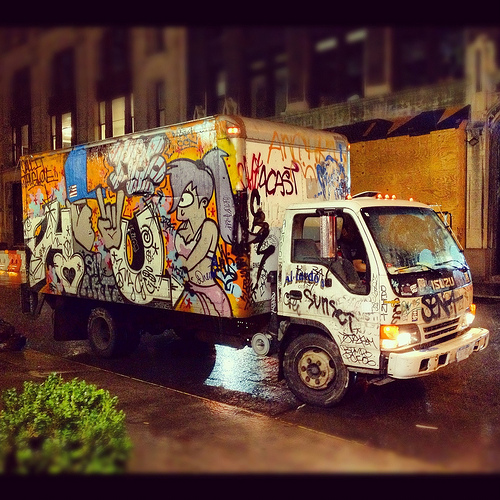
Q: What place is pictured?
A: It is a pavement.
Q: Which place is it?
A: It is a pavement.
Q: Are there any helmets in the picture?
A: No, there are no helmets.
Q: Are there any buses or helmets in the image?
A: No, there are no helmets or buses.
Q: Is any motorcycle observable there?
A: No, there are no motorcycles.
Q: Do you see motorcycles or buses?
A: No, there are no motorcycles or buses.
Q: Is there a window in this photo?
A: Yes, there are windows.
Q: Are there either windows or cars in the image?
A: Yes, there are windows.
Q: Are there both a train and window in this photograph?
A: No, there are windows but no trains.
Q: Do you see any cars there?
A: No, there are no cars.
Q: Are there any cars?
A: No, there are no cars.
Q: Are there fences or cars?
A: No, there are no cars or fences.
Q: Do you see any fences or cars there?
A: No, there are no cars or fences.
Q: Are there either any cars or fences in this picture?
A: No, there are no cars or fences.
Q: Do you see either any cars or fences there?
A: No, there are no cars or fences.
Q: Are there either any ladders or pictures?
A: No, there are no pictures or ladders.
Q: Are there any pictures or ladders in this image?
A: No, there are no pictures or ladders.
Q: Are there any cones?
A: No, there are no cones.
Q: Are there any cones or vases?
A: No, there are no cones or vases.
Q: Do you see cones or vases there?
A: No, there are no cones or vases.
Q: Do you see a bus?
A: No, there are no buses.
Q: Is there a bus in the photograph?
A: No, there are no buses.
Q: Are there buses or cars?
A: No, there are no buses or cars.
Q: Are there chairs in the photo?
A: No, there are no chairs.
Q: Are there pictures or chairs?
A: No, there are no chairs or pictures.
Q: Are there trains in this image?
A: No, there are no trains.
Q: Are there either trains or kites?
A: No, there are no trains or kites.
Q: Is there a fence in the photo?
A: No, there are no fences.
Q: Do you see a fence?
A: No, there are no fences.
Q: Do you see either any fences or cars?
A: No, there are no fences or cars.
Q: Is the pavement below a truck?
A: Yes, the pavement is below a truck.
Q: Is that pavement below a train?
A: No, the pavement is below a truck.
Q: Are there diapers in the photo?
A: No, there are no diapers.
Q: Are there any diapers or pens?
A: No, there are no diapers or pens.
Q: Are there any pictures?
A: No, there are no pictures.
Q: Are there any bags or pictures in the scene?
A: No, there are no pictures or bags.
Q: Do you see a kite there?
A: No, there are no kites.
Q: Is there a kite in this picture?
A: No, there are no kites.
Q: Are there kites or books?
A: No, there are no kites or books.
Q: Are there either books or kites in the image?
A: No, there are no kites or books.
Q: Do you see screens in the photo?
A: No, there are no screens.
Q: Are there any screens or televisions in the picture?
A: No, there are no screens or televisions.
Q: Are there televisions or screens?
A: No, there are no screens or televisions.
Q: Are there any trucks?
A: Yes, there is a truck.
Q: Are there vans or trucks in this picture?
A: Yes, there is a truck.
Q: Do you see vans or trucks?
A: Yes, there is a truck.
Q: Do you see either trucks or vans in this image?
A: Yes, there is a truck.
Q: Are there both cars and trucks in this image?
A: No, there is a truck but no cars.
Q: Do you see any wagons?
A: No, there are no wagons.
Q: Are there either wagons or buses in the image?
A: No, there are no wagons or buses.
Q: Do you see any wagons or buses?
A: No, there are no wagons or buses.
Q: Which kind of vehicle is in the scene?
A: The vehicle is a truck.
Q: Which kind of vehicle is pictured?
A: The vehicle is a truck.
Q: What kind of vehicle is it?
A: The vehicle is a truck.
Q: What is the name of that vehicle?
A: That is a truck.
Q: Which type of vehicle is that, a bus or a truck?
A: That is a truck.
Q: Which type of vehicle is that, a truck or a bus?
A: That is a truck.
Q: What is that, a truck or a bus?
A: That is a truck.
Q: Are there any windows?
A: Yes, there is a window.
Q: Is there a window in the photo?
A: Yes, there is a window.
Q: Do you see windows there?
A: Yes, there is a window.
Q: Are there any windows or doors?
A: Yes, there is a window.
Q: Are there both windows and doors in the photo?
A: Yes, there are both a window and doors.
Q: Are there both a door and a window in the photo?
A: Yes, there are both a window and a door.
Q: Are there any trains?
A: No, there are no trains.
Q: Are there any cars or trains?
A: No, there are no trains or cars.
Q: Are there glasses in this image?
A: No, there are no glasses.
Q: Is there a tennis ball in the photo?
A: No, there are no tennis balls.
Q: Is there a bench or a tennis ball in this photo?
A: No, there are no tennis balls or benches.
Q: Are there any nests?
A: No, there are no nests.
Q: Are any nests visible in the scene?
A: No, there are no nests.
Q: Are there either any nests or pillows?
A: No, there are no nests or pillows.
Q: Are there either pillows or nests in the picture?
A: No, there are no nests or pillows.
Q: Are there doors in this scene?
A: Yes, there is a door.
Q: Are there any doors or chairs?
A: Yes, there is a door.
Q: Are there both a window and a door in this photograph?
A: Yes, there are both a door and a window.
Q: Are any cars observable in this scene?
A: No, there are no cars.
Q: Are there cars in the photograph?
A: No, there are no cars.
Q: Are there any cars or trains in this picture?
A: No, there are no cars or trains.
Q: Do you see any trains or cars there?
A: No, there are no cars or trains.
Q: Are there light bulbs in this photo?
A: No, there are no light bulbs.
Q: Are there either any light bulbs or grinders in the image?
A: No, there are no light bulbs or grinders.